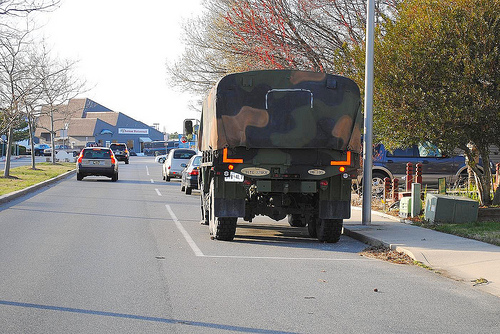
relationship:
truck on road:
[179, 61, 363, 257] [140, 155, 215, 245]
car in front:
[180, 155, 236, 205] [175, 139, 299, 218]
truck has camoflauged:
[179, 61, 363, 257] [174, 62, 378, 174]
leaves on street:
[350, 227, 432, 286] [124, 168, 190, 256]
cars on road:
[67, 110, 204, 210] [140, 155, 215, 245]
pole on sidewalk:
[353, 0, 386, 236] [357, 203, 466, 257]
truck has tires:
[179, 61, 363, 257] [191, 184, 349, 250]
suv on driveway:
[358, 129, 488, 210] [346, 85, 497, 188]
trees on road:
[2, 36, 59, 172] [140, 155, 215, 245]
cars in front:
[67, 110, 204, 210] [175, 139, 299, 218]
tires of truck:
[191, 184, 349, 250] [179, 61, 363, 257]